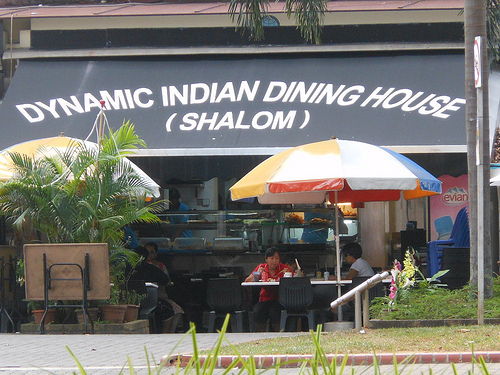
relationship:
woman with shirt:
[246, 245, 294, 333] [251, 263, 294, 303]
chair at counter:
[205, 277, 250, 333] [241, 281, 357, 284]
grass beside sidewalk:
[198, 323, 500, 354] [1, 332, 300, 375]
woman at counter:
[246, 245, 294, 333] [241, 281, 357, 284]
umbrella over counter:
[226, 136, 444, 204] [241, 281, 357, 284]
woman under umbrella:
[246, 245, 294, 333] [226, 136, 444, 204]